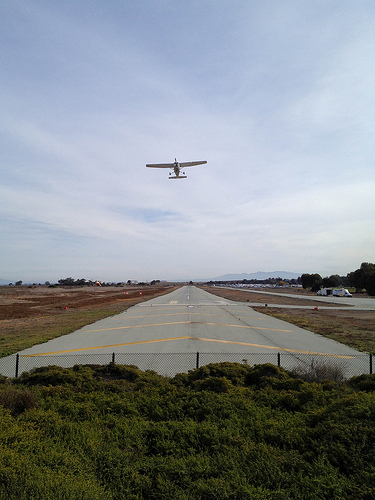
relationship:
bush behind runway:
[189, 279, 194, 285] [1, 286, 374, 379]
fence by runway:
[2, 352, 374, 374] [1, 286, 374, 379]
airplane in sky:
[145, 159, 207, 181] [1, 0, 374, 284]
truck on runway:
[334, 287, 355, 299] [220, 285, 374, 310]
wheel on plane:
[181, 171, 186, 176] [145, 159, 207, 181]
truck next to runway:
[334, 287, 355, 299] [1, 286, 374, 379]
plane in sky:
[145, 159, 207, 181] [1, 0, 374, 284]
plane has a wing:
[145, 159, 207, 181] [146, 163, 175, 168]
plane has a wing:
[145, 159, 207, 181] [178, 159, 208, 168]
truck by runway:
[334, 287, 355, 299] [1, 286, 374, 379]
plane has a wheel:
[145, 159, 207, 181] [181, 171, 186, 176]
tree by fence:
[299, 358, 350, 385] [2, 352, 374, 374]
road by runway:
[251, 298, 352, 317] [1, 286, 374, 379]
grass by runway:
[263, 308, 374, 354] [1, 286, 374, 379]